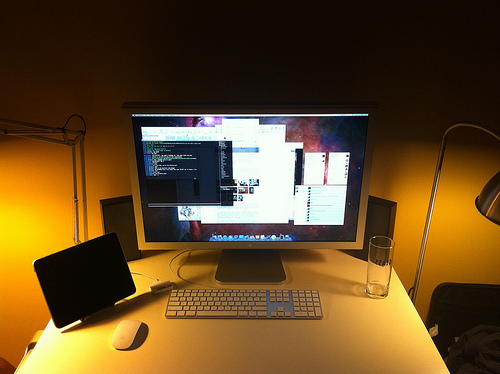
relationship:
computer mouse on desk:
[112, 318, 149, 350] [47, 188, 454, 362]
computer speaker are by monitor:
[99, 194, 143, 261] [105, 116, 401, 270]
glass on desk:
[341, 219, 420, 303] [47, 188, 454, 362]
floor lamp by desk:
[412, 95, 493, 347] [47, 188, 454, 362]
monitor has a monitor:
[105, 116, 401, 270] [131, 114, 369, 242]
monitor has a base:
[105, 116, 401, 270] [214, 256, 298, 289]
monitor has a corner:
[105, 116, 401, 270] [328, 81, 380, 131]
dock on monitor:
[207, 223, 305, 239] [131, 114, 369, 242]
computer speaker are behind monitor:
[99, 194, 143, 261] [105, 116, 401, 270]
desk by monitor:
[13, 249, 451, 373] [105, 116, 401, 270]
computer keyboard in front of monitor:
[164, 288, 323, 319] [105, 116, 401, 270]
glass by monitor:
[341, 219, 420, 303] [105, 116, 401, 270]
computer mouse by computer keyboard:
[112, 318, 149, 350] [164, 288, 323, 319]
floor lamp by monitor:
[412, 95, 493, 347] [105, 116, 401, 270]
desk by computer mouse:
[13, 249, 451, 373] [112, 318, 149, 350]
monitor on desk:
[105, 116, 401, 270] [47, 188, 454, 362]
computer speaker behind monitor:
[99, 194, 143, 261] [105, 116, 401, 270]